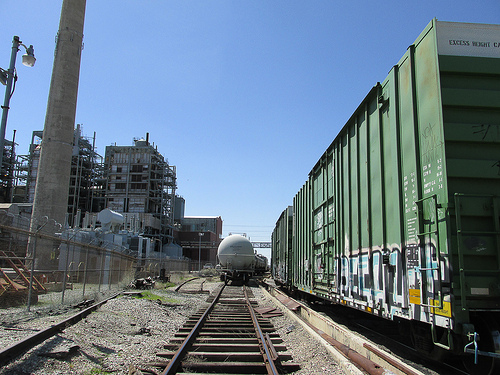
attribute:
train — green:
[272, 31, 466, 319]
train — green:
[324, 110, 481, 298]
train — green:
[265, 27, 462, 343]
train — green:
[263, 33, 471, 330]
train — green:
[304, 32, 464, 338]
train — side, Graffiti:
[326, 230, 473, 327]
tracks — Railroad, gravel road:
[177, 270, 270, 372]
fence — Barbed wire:
[32, 230, 132, 282]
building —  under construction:
[26, 112, 195, 282]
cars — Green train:
[277, 10, 483, 350]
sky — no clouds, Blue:
[177, 23, 364, 88]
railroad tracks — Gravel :
[160, 277, 290, 373]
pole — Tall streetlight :
[24, 8, 86, 238]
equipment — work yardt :
[10, 143, 153, 276]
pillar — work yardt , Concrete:
[30, 8, 161, 290]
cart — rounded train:
[204, 226, 273, 288]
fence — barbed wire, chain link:
[2, 204, 173, 317]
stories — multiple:
[126, 153, 149, 214]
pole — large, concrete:
[23, 0, 99, 283]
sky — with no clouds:
[110, 10, 356, 110]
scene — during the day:
[1, 4, 483, 370]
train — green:
[273, 17, 484, 360]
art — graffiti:
[323, 239, 451, 324]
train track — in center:
[152, 276, 289, 370]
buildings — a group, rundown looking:
[0, 121, 222, 271]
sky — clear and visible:
[88, 1, 364, 98]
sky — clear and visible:
[189, 95, 288, 200]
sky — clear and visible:
[87, 39, 201, 124]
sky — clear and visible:
[0, 1, 59, 36]